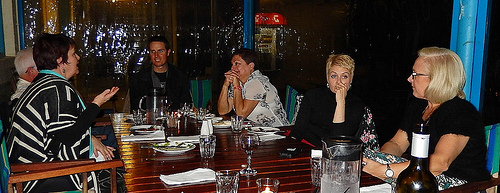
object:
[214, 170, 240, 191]
glass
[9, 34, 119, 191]
person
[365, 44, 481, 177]
person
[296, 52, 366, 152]
person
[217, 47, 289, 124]
person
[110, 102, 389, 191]
table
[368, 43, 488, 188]
woman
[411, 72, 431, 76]
eye glasses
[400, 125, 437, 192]
bottle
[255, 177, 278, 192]
cup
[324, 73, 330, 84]
ear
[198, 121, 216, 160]
glass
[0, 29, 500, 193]
table/people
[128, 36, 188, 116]
man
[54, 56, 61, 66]
earring